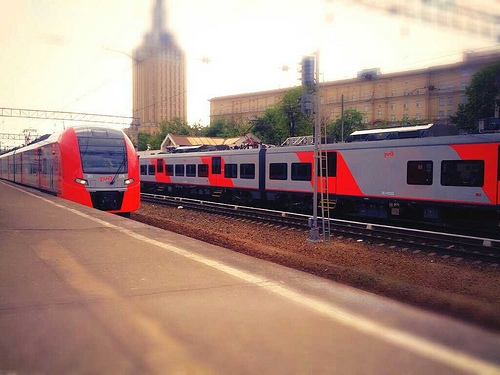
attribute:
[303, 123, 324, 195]
pole — white